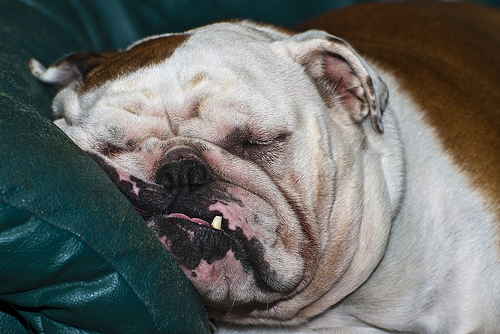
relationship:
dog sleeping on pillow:
[64, 20, 473, 331] [1, 0, 212, 330]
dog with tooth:
[64, 20, 473, 331] [210, 213, 225, 232]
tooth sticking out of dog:
[210, 215, 222, 227] [64, 20, 473, 331]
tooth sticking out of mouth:
[210, 215, 222, 227] [131, 190, 306, 295]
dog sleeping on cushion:
[64, 20, 473, 331] [4, 1, 174, 332]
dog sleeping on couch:
[64, 20, 473, 331] [5, 1, 214, 331]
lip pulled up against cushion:
[172, 196, 294, 293] [7, 71, 189, 330]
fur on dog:
[369, 60, 484, 301] [64, 20, 473, 331]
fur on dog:
[408, 43, 468, 99] [64, 20, 473, 331]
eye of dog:
[233, 128, 295, 165] [64, 20, 473, 331]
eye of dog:
[98, 137, 136, 157] [64, 20, 473, 331]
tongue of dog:
[162, 211, 213, 227] [28, 20, 480, 323]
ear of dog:
[279, 24, 395, 130] [64, 20, 473, 331]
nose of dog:
[135, 141, 242, 213] [64, 20, 473, 331]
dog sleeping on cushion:
[64, 20, 473, 331] [0, 14, 227, 332]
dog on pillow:
[64, 20, 473, 331] [31, 75, 98, 273]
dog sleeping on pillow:
[64, 20, 473, 331] [1, 0, 356, 333]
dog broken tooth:
[64, 20, 473, 331] [208, 213, 223, 228]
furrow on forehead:
[99, 62, 226, 147] [54, 65, 329, 135]